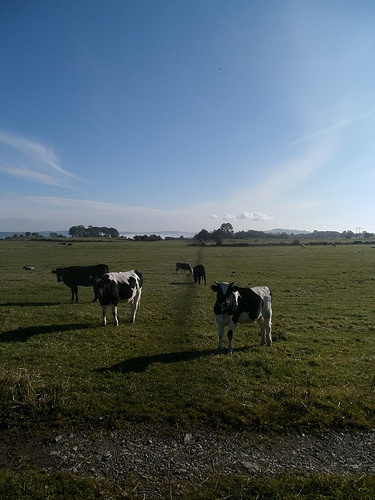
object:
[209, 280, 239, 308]
head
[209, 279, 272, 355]
cow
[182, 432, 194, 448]
rocks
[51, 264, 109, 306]
cow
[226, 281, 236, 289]
horn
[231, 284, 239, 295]
ear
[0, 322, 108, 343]
shadow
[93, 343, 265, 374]
shadow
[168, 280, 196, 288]
shadow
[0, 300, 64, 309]
shadow